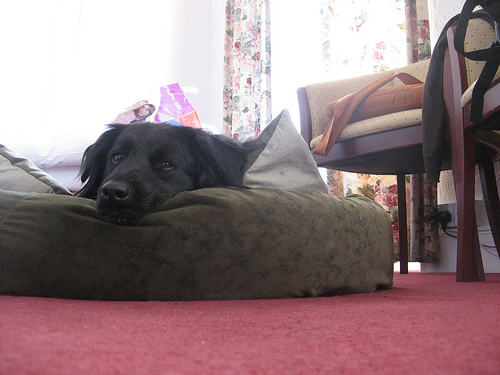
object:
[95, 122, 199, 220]
head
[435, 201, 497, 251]
power cord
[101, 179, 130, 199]
nose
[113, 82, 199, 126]
bag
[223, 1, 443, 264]
drapes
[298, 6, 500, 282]
chair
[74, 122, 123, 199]
ear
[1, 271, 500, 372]
floor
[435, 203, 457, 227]
outlet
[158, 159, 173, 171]
eye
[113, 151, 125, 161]
eye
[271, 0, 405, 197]
window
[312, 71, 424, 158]
bag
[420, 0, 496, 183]
jacket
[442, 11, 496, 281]
chair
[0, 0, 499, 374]
room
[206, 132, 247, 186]
ear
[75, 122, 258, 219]
dog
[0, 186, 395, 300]
bed